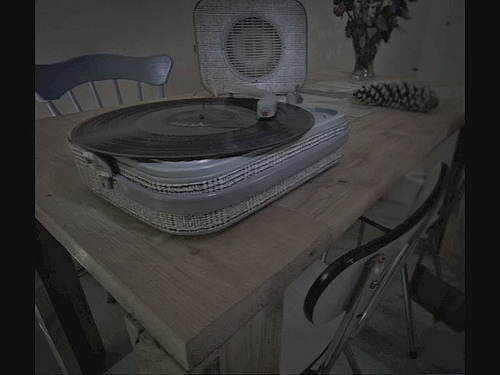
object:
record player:
[65, 81, 351, 239]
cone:
[352, 81, 438, 114]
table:
[34, 68, 468, 375]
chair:
[34, 53, 173, 117]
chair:
[280, 161, 448, 375]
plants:
[332, 1, 364, 76]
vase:
[348, 27, 382, 82]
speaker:
[194, 0, 308, 97]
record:
[67, 96, 315, 160]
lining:
[65, 106, 349, 235]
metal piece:
[317, 255, 386, 375]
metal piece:
[356, 242, 413, 326]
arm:
[214, 82, 278, 119]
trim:
[303, 162, 449, 324]